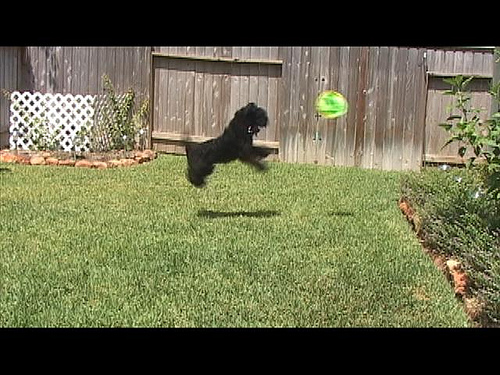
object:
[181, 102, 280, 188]
dog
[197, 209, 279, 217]
shadow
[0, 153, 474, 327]
grass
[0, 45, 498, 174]
fence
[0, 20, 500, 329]
yard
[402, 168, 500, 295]
shrub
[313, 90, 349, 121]
ball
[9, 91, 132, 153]
trellis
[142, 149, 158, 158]
stone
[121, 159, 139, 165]
stone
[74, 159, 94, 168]
stone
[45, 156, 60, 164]
stone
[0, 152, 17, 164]
stone